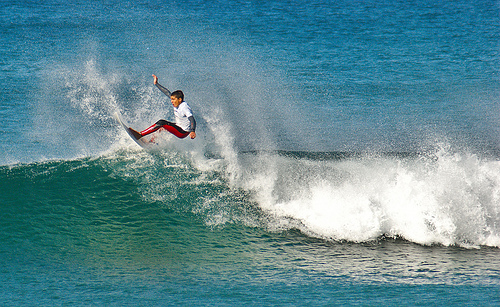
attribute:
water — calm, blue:
[1, 0, 498, 305]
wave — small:
[2, 139, 499, 249]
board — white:
[114, 110, 164, 158]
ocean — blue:
[5, 36, 490, 154]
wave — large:
[184, 141, 473, 252]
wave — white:
[246, 144, 496, 241]